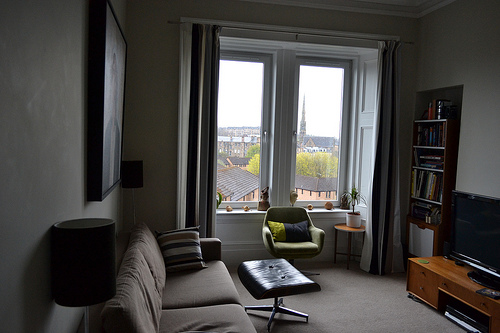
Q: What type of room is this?
A: It is a living room.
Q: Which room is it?
A: It is a living room.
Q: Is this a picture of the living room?
A: Yes, it is showing the living room.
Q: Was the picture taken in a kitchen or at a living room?
A: It was taken at a living room.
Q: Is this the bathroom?
A: No, it is the living room.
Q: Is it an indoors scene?
A: Yes, it is indoors.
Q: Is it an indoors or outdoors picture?
A: It is indoors.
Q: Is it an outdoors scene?
A: No, it is indoors.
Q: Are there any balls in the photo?
A: No, there are no balls.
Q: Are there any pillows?
A: Yes, there is a pillow.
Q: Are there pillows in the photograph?
A: Yes, there is a pillow.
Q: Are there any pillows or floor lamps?
A: Yes, there is a pillow.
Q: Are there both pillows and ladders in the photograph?
A: No, there is a pillow but no ladders.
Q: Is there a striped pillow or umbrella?
A: Yes, there is a striped pillow.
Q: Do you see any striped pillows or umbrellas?
A: Yes, there is a striped pillow.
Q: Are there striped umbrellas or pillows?
A: Yes, there is a striped pillow.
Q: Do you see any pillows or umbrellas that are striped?
A: Yes, the pillow is striped.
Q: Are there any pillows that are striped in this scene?
A: Yes, there is a striped pillow.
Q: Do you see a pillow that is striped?
A: Yes, there is a pillow that is striped.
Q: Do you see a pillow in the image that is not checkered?
A: Yes, there is a striped pillow.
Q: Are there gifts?
A: No, there are no gifts.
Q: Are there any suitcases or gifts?
A: No, there are no gifts or suitcases.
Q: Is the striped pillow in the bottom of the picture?
A: Yes, the pillow is in the bottom of the image.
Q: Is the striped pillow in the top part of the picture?
A: No, the pillow is in the bottom of the image.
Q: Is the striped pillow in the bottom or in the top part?
A: The pillow is in the bottom of the image.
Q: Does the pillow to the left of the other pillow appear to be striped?
A: Yes, the pillow is striped.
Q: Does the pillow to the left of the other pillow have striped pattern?
A: Yes, the pillow is striped.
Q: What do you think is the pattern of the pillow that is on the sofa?
A: The pillow is striped.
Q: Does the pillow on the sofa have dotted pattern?
A: No, the pillow is striped.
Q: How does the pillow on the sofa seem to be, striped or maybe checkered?
A: The pillow is striped.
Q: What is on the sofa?
A: The pillow is on the sofa.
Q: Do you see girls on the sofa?
A: No, there is a pillow on the sofa.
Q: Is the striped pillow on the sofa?
A: Yes, the pillow is on the sofa.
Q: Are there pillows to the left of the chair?
A: Yes, there is a pillow to the left of the chair.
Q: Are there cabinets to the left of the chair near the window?
A: No, there is a pillow to the left of the chair.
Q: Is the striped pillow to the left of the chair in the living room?
A: Yes, the pillow is to the left of the chair.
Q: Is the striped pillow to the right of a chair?
A: No, the pillow is to the left of a chair.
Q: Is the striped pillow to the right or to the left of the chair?
A: The pillow is to the left of the chair.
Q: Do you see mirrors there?
A: No, there are no mirrors.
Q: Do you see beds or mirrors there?
A: No, there are no mirrors or beds.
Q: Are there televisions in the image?
A: Yes, there is a television.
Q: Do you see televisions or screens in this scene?
A: Yes, there is a television.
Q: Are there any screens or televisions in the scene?
A: Yes, there is a television.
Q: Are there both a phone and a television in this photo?
A: No, there is a television but no phones.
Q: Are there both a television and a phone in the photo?
A: No, there is a television but no phones.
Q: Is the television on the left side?
A: No, the television is on the right of the image.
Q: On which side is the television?
A: The television is on the right of the image.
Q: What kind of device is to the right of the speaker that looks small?
A: The device is a television.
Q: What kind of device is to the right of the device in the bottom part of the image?
A: The device is a television.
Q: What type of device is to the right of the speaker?
A: The device is a television.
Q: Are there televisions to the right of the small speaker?
A: Yes, there is a television to the right of the speaker.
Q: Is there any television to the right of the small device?
A: Yes, there is a television to the right of the speaker.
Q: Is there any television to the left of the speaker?
A: No, the television is to the right of the speaker.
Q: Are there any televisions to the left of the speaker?
A: No, the television is to the right of the speaker.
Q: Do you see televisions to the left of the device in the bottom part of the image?
A: No, the television is to the right of the speaker.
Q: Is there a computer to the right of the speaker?
A: No, there is a television to the right of the speaker.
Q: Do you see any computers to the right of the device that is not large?
A: No, there is a television to the right of the speaker.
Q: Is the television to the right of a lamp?
A: No, the television is to the right of a speaker.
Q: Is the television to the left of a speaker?
A: No, the television is to the right of a speaker.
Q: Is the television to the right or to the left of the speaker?
A: The television is to the right of the speaker.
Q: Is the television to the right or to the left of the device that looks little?
A: The television is to the right of the speaker.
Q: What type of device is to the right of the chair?
A: The device is a television.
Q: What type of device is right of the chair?
A: The device is a television.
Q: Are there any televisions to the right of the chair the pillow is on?
A: Yes, there is a television to the right of the chair.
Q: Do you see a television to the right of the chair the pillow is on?
A: Yes, there is a television to the right of the chair.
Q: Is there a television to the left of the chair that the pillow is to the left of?
A: No, the television is to the right of the chair.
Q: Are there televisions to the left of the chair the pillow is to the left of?
A: No, the television is to the right of the chair.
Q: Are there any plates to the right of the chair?
A: No, there is a television to the right of the chair.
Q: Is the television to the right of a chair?
A: Yes, the television is to the right of a chair.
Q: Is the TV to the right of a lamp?
A: No, the TV is to the right of a chair.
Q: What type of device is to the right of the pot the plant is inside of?
A: The device is a television.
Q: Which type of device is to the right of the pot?
A: The device is a television.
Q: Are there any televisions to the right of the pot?
A: Yes, there is a television to the right of the pot.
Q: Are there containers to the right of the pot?
A: No, there is a television to the right of the pot.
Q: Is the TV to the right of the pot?
A: Yes, the TV is to the right of the pot.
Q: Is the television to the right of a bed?
A: No, the television is to the right of the pot.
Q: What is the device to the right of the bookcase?
A: The device is a television.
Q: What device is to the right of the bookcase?
A: The device is a television.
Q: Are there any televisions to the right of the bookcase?
A: Yes, there is a television to the right of the bookcase.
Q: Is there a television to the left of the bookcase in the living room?
A: No, the television is to the right of the bookcase.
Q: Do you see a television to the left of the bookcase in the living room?
A: No, the television is to the right of the bookcase.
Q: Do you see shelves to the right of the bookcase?
A: No, there is a television to the right of the bookcase.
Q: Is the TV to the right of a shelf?
A: No, the TV is to the right of the bookcase.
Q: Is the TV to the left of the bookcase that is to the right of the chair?
A: No, the TV is to the right of the bookcase.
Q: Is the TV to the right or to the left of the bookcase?
A: The TV is to the right of the bookcase.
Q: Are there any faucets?
A: No, there are no faucets.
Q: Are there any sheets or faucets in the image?
A: No, there are no faucets or sheets.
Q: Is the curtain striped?
A: Yes, the curtain is striped.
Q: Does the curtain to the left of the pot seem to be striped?
A: Yes, the curtain is striped.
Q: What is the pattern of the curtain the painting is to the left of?
A: The curtain is striped.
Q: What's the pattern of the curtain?
A: The curtain is striped.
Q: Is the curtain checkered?
A: No, the curtain is striped.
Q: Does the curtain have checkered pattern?
A: No, the curtain is striped.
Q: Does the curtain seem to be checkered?
A: No, the curtain is striped.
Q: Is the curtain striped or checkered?
A: The curtain is striped.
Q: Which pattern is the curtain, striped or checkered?
A: The curtain is striped.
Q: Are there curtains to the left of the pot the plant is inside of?
A: Yes, there is a curtain to the left of the pot.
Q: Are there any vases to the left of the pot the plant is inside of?
A: No, there is a curtain to the left of the pot.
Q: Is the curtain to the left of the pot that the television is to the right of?
A: Yes, the curtain is to the left of the pot.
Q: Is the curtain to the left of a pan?
A: No, the curtain is to the left of the pot.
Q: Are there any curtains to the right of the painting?
A: Yes, there is a curtain to the right of the painting.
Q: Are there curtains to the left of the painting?
A: No, the curtain is to the right of the painting.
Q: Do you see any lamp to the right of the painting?
A: No, there is a curtain to the right of the painting.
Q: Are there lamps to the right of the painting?
A: No, there is a curtain to the right of the painting.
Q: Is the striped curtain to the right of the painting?
A: Yes, the curtain is to the right of the painting.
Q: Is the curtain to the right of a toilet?
A: No, the curtain is to the right of the painting.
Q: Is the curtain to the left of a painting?
A: No, the curtain is to the right of a painting.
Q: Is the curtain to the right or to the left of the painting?
A: The curtain is to the right of the painting.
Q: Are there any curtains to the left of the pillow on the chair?
A: Yes, there is a curtain to the left of the pillow.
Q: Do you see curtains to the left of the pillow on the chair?
A: Yes, there is a curtain to the left of the pillow.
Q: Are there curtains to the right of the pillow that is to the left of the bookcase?
A: No, the curtain is to the left of the pillow.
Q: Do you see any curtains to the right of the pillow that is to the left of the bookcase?
A: No, the curtain is to the left of the pillow.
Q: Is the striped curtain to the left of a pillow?
A: Yes, the curtain is to the left of a pillow.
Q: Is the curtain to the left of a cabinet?
A: No, the curtain is to the left of a pillow.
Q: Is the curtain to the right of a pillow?
A: No, the curtain is to the left of a pillow.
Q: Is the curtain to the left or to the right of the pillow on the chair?
A: The curtain is to the left of the pillow.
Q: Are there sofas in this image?
A: Yes, there is a sofa.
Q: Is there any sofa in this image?
A: Yes, there is a sofa.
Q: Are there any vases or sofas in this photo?
A: Yes, there is a sofa.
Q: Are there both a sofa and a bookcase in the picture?
A: Yes, there are both a sofa and a bookcase.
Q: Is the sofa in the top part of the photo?
A: No, the sofa is in the bottom of the image.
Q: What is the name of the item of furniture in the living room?
A: The piece of furniture is a sofa.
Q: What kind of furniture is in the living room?
A: The piece of furniture is a sofa.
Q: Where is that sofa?
A: The sofa is in the living room.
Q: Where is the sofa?
A: The sofa is in the living room.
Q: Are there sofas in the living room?
A: Yes, there is a sofa in the living room.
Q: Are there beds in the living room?
A: No, there is a sofa in the living room.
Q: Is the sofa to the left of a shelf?
A: No, the sofa is to the left of the pillow.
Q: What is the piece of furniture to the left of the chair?
A: The piece of furniture is a sofa.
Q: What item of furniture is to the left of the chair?
A: The piece of furniture is a sofa.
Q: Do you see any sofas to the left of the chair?
A: Yes, there is a sofa to the left of the chair.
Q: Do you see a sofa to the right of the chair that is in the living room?
A: No, the sofa is to the left of the chair.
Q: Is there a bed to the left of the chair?
A: No, there is a sofa to the left of the chair.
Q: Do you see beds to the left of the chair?
A: No, there is a sofa to the left of the chair.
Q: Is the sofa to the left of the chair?
A: Yes, the sofa is to the left of the chair.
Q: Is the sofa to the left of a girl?
A: No, the sofa is to the left of the chair.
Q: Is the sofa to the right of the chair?
A: No, the sofa is to the left of the chair.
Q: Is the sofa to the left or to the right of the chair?
A: The sofa is to the left of the chair.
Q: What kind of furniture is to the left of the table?
A: The piece of furniture is a sofa.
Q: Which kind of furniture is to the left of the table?
A: The piece of furniture is a sofa.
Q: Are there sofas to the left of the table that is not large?
A: Yes, there is a sofa to the left of the table.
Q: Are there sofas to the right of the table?
A: No, the sofa is to the left of the table.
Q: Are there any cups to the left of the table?
A: No, there is a sofa to the left of the table.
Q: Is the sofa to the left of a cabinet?
A: No, the sofa is to the left of a table.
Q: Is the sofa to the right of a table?
A: No, the sofa is to the left of a table.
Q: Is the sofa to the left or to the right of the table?
A: The sofa is to the left of the table.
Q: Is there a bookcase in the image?
A: Yes, there is a bookcase.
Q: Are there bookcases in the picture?
A: Yes, there is a bookcase.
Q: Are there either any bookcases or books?
A: Yes, there is a bookcase.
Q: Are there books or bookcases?
A: Yes, there is a bookcase.